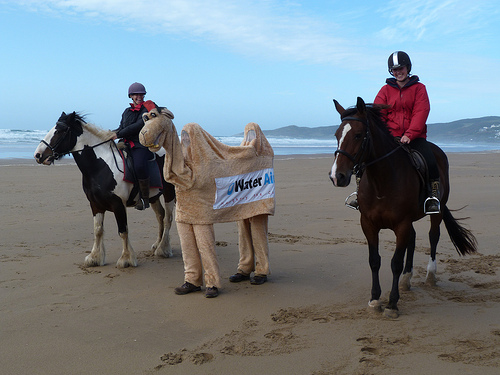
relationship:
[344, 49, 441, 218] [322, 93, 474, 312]
person riding horse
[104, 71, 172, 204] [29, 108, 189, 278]
person riding horse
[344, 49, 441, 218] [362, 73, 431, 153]
person wearing jacket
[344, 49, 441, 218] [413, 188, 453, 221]
person using stirrup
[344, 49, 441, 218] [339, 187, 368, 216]
person using stirrup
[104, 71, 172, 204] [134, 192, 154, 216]
person using stirrup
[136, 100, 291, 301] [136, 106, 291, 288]
people wearing costume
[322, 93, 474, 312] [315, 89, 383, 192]
horse has head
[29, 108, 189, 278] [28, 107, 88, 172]
horse has head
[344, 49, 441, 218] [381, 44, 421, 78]
person wearing helmet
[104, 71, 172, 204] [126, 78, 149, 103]
person wearing helmet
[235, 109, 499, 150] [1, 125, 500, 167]
foot hill behind water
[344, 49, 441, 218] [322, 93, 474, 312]
person on horse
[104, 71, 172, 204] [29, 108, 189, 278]
person on horse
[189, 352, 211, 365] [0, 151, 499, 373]
footprint on sand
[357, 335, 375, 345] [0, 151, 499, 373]
footprint on sand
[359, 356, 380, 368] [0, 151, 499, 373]
footprint on sand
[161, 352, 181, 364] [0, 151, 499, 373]
footprint on sand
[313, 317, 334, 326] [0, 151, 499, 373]
footprint on sand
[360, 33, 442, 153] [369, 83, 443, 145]
person wearing jacket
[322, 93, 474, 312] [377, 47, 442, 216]
horse with rider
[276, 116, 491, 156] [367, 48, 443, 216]
hill behind rider